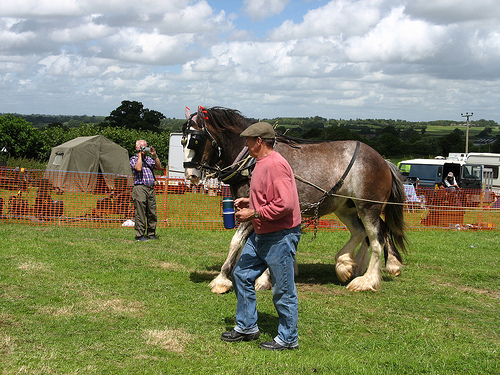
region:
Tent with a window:
[40, 126, 140, 194]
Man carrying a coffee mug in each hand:
[183, 120, 317, 354]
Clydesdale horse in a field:
[161, 98, 486, 296]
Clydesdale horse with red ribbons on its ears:
[163, 95, 410, 367]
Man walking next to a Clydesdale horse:
[166, 89, 413, 361]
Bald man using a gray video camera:
[118, 133, 168, 253]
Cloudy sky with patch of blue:
[120, 0, 445, 65]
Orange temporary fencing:
[0, 161, 493, 224]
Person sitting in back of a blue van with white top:
[395, 153, 485, 203]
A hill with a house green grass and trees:
[325, 105, 497, 155]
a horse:
[144, 88, 452, 316]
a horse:
[202, 104, 369, 356]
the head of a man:
[233, 117, 282, 166]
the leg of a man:
[266, 229, 306, 333]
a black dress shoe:
[254, 329, 301, 356]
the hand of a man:
[232, 200, 264, 225]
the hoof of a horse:
[340, 265, 385, 297]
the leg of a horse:
[358, 193, 391, 272]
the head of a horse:
[169, 96, 226, 193]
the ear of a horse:
[191, 97, 213, 128]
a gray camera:
[135, 142, 155, 156]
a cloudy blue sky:
[1, 2, 498, 124]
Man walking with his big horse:
[172, 97, 415, 350]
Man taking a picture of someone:
[120, 125, 170, 245]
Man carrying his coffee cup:
[213, 117, 299, 229]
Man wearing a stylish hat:
[232, 116, 280, 156]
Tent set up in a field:
[40, 130, 131, 201]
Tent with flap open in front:
[40, 128, 135, 208]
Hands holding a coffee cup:
[213, 192, 246, 232]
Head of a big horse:
[173, 97, 220, 183]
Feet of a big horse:
[321, 235, 396, 296]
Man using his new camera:
[118, 128, 168, 258]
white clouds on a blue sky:
[2, 2, 493, 123]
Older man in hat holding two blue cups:
[219, 112, 300, 369]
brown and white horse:
[172, 96, 423, 282]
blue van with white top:
[393, 144, 489, 228]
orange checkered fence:
[4, 155, 220, 231]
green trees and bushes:
[292, 108, 498, 162]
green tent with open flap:
[36, 118, 136, 207]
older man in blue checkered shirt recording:
[126, 125, 161, 248]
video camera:
[138, 143, 156, 160]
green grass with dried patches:
[3, 218, 185, 373]